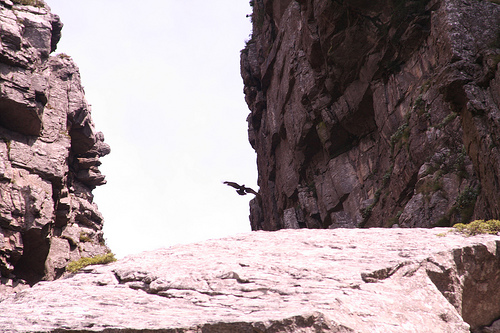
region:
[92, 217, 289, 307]
the rock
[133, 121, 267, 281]
the rock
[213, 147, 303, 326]
the rock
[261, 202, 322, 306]
the rock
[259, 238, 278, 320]
the rock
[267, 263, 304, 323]
the rock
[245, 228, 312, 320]
the rock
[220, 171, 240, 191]
the bird has a wing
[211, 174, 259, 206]
the bird is flying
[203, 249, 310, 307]
the rock is gray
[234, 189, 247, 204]
the bird had a tail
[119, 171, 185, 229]
the sky is gray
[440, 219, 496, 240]
the grass is sparce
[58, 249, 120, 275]
the grass is short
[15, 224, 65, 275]
the shadow is on the rock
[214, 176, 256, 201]
the bird is gliding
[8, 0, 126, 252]
the rocks are high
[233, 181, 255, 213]
bird flying in air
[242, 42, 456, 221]
rocky wall near bird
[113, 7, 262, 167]
sky is light grey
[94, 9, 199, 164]
sky is overcast and cloudy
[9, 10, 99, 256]
wall is rocky and rough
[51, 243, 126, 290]
green grass on wall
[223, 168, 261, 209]
single bird is flying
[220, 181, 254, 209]
bird is between walls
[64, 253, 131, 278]
small plants on rocks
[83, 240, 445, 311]
rocks are light brown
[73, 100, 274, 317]
the rock is rough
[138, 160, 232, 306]
the rock is rough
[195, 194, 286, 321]
the rock is rough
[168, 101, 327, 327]
the rock is rough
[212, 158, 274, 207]
A bird in the air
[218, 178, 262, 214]
a bird with wing spread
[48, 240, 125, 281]
a patch of green grass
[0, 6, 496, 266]
a bird flying between two large rock areas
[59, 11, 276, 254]
a clear white sky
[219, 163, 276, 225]
a black bird is flying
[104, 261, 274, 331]
a crack in top of rock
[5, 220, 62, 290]
a small cave in rock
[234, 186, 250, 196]
tail feathers of a bird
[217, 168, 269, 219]
the black bird flying in the sky